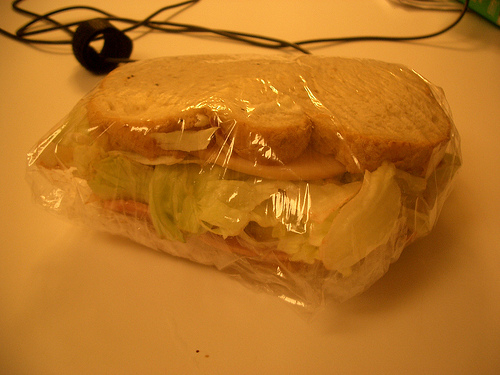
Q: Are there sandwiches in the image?
A: Yes, there is a sandwich.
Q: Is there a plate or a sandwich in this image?
A: Yes, there is a sandwich.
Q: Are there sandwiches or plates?
A: Yes, there is a sandwich.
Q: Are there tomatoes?
A: No, there are no tomatoes.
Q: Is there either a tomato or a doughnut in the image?
A: No, there are no tomatoes or donuts.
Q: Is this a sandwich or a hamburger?
A: This is a sandwich.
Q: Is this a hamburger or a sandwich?
A: This is a sandwich.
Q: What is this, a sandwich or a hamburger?
A: This is a sandwich.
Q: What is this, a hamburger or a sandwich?
A: This is a sandwich.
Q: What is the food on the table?
A: The food is a sandwich.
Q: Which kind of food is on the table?
A: The food is a sandwich.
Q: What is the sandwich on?
A: The sandwich is on the table.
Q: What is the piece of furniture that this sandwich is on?
A: The piece of furniture is a table.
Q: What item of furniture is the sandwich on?
A: The sandwich is on the table.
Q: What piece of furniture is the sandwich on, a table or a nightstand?
A: The sandwich is on a table.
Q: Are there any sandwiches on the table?
A: Yes, there is a sandwich on the table.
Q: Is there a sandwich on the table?
A: Yes, there is a sandwich on the table.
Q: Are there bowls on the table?
A: No, there is a sandwich on the table.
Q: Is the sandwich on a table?
A: Yes, the sandwich is on a table.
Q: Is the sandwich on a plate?
A: No, the sandwich is on a table.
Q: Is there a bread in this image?
A: Yes, there is a bread.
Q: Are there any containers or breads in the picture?
A: Yes, there is a bread.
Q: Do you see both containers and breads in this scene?
A: No, there is a bread but no containers.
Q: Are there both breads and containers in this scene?
A: No, there is a bread but no containers.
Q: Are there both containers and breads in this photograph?
A: No, there is a bread but no containers.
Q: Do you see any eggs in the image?
A: No, there are no eggs.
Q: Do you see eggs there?
A: No, there are no eggs.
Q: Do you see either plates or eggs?
A: No, there are no eggs or plates.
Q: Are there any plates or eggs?
A: No, there are no eggs or plates.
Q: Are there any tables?
A: Yes, there is a table.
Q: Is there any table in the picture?
A: Yes, there is a table.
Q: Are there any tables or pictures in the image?
A: Yes, there is a table.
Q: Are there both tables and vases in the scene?
A: No, there is a table but no vases.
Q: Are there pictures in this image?
A: No, there are no pictures.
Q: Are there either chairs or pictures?
A: No, there are no pictures or chairs.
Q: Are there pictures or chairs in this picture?
A: No, there are no pictures or chairs.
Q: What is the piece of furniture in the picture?
A: The piece of furniture is a table.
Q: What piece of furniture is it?
A: The piece of furniture is a table.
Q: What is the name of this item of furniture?
A: This is a table.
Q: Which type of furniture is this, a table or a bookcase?
A: This is a table.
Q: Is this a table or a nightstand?
A: This is a table.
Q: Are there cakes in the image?
A: No, there are no cakes.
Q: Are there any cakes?
A: No, there are no cakes.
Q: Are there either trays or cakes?
A: No, there are no cakes or trays.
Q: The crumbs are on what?
A: The crumbs are on the table.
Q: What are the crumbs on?
A: The crumbs are on the table.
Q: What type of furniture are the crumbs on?
A: The crumbs are on the table.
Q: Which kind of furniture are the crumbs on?
A: The crumbs are on the table.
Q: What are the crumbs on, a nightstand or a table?
A: The crumbs are on a table.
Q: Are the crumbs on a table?
A: Yes, the crumbs are on a table.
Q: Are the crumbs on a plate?
A: No, the crumbs are on a table.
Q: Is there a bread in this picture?
A: Yes, there is a bread.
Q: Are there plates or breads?
A: Yes, there is a bread.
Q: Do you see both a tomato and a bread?
A: No, there is a bread but no tomatoes.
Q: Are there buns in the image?
A: No, there are no buns.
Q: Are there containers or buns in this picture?
A: No, there are no buns or containers.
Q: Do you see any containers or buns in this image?
A: No, there are no buns or containers.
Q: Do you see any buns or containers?
A: No, there are no buns or containers.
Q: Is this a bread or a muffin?
A: This is a bread.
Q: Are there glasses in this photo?
A: No, there are no glasses.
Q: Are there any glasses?
A: No, there are no glasses.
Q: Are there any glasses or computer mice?
A: No, there are no glasses or computer mice.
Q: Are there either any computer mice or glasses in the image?
A: No, there are no glasses or computer mice.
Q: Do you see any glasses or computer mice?
A: No, there are no glasses or computer mice.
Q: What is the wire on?
A: The wire is on the table.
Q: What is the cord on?
A: The wire is on the table.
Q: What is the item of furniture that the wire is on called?
A: The piece of furniture is a table.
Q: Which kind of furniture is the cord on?
A: The wire is on the table.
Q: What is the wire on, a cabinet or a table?
A: The wire is on a table.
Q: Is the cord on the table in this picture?
A: Yes, the cord is on the table.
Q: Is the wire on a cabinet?
A: No, the wire is on the table.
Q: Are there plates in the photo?
A: No, there are no plates.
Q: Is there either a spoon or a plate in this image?
A: No, there are no plates or spoons.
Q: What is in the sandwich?
A: The ham is in the sandwich.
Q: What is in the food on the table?
A: The ham is in the sandwich.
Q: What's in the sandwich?
A: The ham is in the sandwich.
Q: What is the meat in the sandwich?
A: The meat is ham.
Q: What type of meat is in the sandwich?
A: The meat is ham.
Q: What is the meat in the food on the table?
A: The meat is ham.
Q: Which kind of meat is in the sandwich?
A: The meat is ham.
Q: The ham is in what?
A: The ham is in the sandwich.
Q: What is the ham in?
A: The ham is in the sandwich.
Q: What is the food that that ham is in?
A: The food is a sandwich.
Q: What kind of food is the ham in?
A: The ham is in the sandwich.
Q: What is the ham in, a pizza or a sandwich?
A: The ham is in a sandwich.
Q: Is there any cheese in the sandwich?
A: No, there is ham in the sandwich.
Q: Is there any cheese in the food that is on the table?
A: No, there is ham in the sandwich.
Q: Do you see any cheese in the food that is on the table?
A: No, there is ham in the sandwich.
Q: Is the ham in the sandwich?
A: Yes, the ham is in the sandwich.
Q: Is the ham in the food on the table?
A: Yes, the ham is in the sandwich.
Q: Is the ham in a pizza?
A: No, the ham is in the sandwich.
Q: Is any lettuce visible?
A: Yes, there is lettuce.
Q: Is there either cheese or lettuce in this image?
A: Yes, there is lettuce.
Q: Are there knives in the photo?
A: No, there are no knives.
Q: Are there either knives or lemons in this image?
A: No, there are no knives or lemons.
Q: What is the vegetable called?
A: The vegetable is lettuce.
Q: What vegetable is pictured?
A: The vegetable is lettuce.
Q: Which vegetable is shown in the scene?
A: The vegetable is lettuce.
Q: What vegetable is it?
A: The vegetable is lettuce.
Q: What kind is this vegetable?
A: This is lettuce.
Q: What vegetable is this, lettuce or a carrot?
A: This is lettuce.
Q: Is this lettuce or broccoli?
A: This is lettuce.